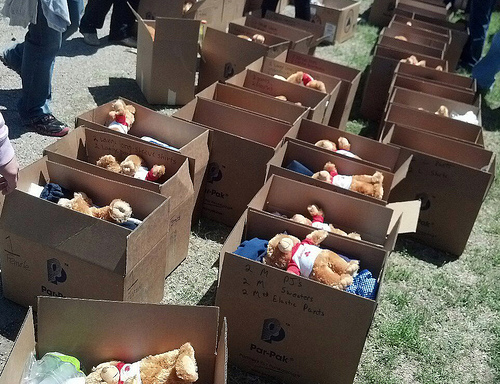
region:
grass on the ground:
[399, 295, 470, 373]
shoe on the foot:
[15, 115, 60, 132]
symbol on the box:
[22, 260, 67, 288]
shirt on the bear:
[297, 236, 312, 271]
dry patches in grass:
[451, 317, 473, 368]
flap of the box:
[380, 197, 422, 245]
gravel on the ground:
[62, 55, 103, 95]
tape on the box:
[165, 85, 180, 105]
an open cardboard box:
[213, 213, 383, 383]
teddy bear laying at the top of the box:
[310, 160, 385, 202]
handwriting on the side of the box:
[229, 257, 338, 327]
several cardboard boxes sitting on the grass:
[1, 0, 497, 382]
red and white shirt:
[285, 238, 320, 274]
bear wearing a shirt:
[309, 163, 389, 202]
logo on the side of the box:
[258, 312, 289, 348]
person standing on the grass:
[3, 1, 75, 148]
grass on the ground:
[2, 0, 499, 382]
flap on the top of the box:
[121, 201, 175, 267]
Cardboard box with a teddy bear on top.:
[213, 210, 388, 382]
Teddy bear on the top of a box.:
[263, 218, 363, 292]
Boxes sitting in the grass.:
[6, 107, 212, 307]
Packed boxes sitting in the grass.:
[3, 126, 193, 316]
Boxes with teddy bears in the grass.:
[217, 146, 397, 382]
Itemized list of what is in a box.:
[236, 261, 331, 316]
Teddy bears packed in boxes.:
[58, 136, 169, 239]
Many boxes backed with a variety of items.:
[5, 110, 410, 378]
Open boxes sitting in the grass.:
[0, 123, 185, 323]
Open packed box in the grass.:
[0, 162, 170, 312]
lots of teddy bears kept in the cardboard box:
[33, 68, 426, 369]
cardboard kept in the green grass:
[227, 180, 493, 375]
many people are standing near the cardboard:
[2, 0, 157, 180]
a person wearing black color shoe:
[18, 103, 70, 142]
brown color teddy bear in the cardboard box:
[276, 232, 343, 284]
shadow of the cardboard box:
[106, 75, 140, 98]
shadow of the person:
[63, 33, 90, 58]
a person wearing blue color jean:
[481, 30, 499, 102]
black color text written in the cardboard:
[246, 317, 296, 378]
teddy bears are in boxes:
[19, 3, 496, 368]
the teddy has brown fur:
[258, 220, 359, 295]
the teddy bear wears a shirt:
[285, 233, 324, 283]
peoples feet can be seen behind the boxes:
[0, 3, 146, 169]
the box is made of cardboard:
[233, 203, 378, 375]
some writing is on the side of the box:
[221, 257, 336, 329]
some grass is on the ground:
[2, 24, 499, 376]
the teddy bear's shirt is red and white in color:
[286, 240, 334, 269]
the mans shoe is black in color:
[29, 105, 70, 140]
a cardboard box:
[209, 223, 382, 378]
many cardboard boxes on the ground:
[29, 5, 489, 376]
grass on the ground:
[395, 260, 486, 380]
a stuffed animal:
[269, 235, 353, 286]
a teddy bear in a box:
[215, 214, 366, 374]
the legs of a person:
[13, 6, 65, 121]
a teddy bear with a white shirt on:
[267, 232, 345, 286]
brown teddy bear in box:
[88, 343, 196, 381]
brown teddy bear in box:
[263, 225, 360, 287]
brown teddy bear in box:
[51, 180, 135, 224]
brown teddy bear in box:
[99, 147, 163, 183]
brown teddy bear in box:
[103, 99, 136, 139]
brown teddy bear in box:
[287, 193, 359, 240]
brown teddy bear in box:
[311, 161, 384, 199]